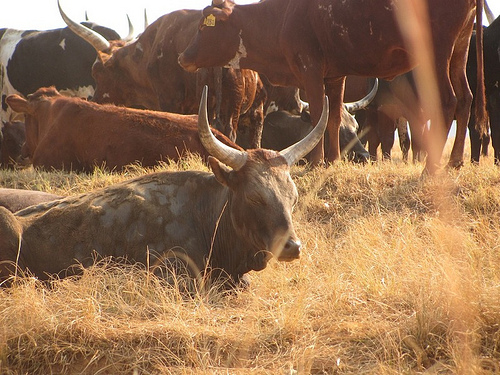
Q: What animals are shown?
A: Cows.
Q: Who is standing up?
A: The cow.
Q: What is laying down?
A: Cow.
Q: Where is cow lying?
A: On ground.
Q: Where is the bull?
A: Lying on ground.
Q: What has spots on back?
A: The bull.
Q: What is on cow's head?
A: Horns.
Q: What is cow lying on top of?
A: Dead grass.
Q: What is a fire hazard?
A: The grass.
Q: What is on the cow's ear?
A: Yellow tag.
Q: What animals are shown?
A: Cattle.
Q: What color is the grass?
A: Brown.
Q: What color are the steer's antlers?
A: White.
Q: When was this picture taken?
A: Daytime.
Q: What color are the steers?
A: Brown, white and grey.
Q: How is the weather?
A: Clear.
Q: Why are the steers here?
A: To graze.